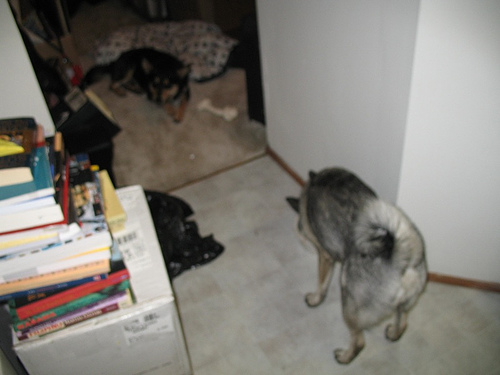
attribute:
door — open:
[9, 2, 269, 202]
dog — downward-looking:
[270, 160, 448, 372]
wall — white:
[273, 44, 453, 160]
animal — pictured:
[287, 159, 427, 365]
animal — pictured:
[75, 44, 188, 118]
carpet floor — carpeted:
[36, 2, 273, 194]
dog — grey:
[286, 168, 428, 367]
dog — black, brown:
[72, 42, 207, 125]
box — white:
[1, 177, 212, 373]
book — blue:
[0, 112, 57, 202]